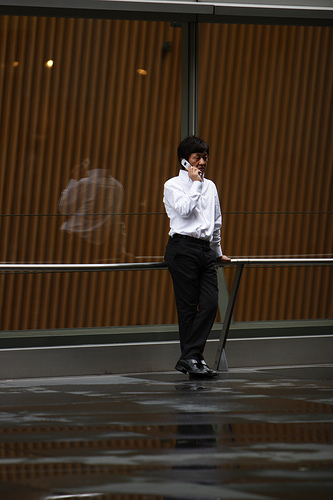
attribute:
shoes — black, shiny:
[176, 355, 220, 382]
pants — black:
[163, 234, 219, 357]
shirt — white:
[164, 169, 228, 257]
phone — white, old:
[181, 156, 197, 172]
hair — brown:
[178, 135, 211, 160]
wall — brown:
[0, 7, 332, 332]